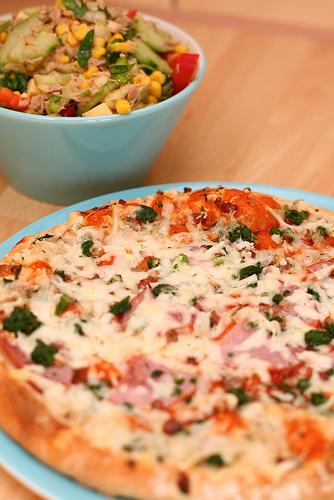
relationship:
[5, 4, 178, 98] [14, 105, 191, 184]
meat and veggies in a bowl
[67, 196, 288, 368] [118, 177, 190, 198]
pizza on a plate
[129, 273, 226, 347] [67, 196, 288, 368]
cheese on a pizza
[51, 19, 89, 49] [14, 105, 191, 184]
corn in a bowl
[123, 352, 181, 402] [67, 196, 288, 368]
ham on a pizza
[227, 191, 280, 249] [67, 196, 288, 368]
sauce on a pizza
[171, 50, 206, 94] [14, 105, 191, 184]
red pepper in a bowl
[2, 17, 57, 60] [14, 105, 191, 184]
cucumber in a bowl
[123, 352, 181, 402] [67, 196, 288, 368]
ham topping on pizza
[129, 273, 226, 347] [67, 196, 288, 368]
cheese on pizza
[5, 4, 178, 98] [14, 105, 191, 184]
salad in a bowl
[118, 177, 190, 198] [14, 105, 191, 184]
plate and bowl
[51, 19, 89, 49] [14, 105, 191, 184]
corn in bowl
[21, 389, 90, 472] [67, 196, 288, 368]
crust of pizza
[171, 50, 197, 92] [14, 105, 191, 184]
red pepper in bowl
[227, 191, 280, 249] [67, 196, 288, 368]
sauce on pizza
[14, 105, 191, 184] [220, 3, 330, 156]
bowl on table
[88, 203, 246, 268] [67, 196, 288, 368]
portion of a pizza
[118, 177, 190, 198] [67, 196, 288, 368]
plate holding pizza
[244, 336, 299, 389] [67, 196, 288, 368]
bacon on pizza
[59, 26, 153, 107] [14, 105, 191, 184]
vegetable salad in bowl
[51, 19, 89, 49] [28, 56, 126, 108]
corn on salad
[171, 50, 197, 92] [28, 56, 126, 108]
red pepper in salad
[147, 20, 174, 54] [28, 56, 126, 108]
carrot in salad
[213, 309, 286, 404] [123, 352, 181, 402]
chunks of ham